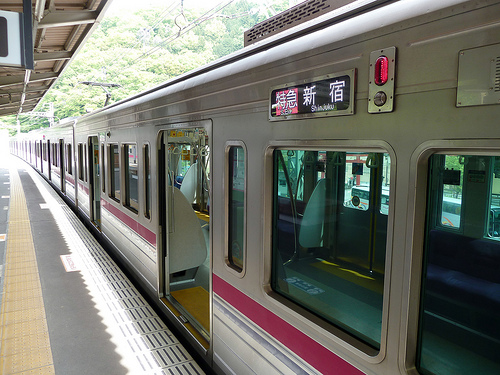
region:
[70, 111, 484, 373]
The train is parked at the station.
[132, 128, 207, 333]
The door is open on the train.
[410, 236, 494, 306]
The seats in the train are blue.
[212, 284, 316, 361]
The train has a red line across the side.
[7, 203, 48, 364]
Part of the sidewalk is yellow.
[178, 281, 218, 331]
The doorway step is yellow.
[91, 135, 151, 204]
The train has windows.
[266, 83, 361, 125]
The sign is in Chinese.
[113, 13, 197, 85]
Wires are above the train.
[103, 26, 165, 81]
The green trees are in the background.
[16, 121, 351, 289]
The train has windows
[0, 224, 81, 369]
The floor is tiled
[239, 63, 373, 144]
The train has characters on it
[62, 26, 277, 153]
The trees are in the back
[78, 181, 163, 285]
The train has a red stripe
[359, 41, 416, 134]
The light is off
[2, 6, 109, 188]
The ceiling covers the floor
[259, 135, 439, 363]
No one is in this window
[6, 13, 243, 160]
Trees are growing in the back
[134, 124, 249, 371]
The door is open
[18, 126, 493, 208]
The train is large.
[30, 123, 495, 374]
Many windows are on the train.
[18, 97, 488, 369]
The train is grey and red.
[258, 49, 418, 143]
The lettering is lit up.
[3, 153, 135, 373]
The station is barren.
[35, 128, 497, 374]
There is no one on the train.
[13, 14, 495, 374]
It is a nice and clear day.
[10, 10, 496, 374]
The train is not moving.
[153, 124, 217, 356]
The door is open.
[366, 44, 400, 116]
The light is red.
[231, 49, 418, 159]
the writing is japanese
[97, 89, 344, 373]
a subway train car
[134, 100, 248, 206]
subway hanger straps in a car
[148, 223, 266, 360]
the train has a yellow step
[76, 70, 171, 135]
power lines for the train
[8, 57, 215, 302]
the train is at a station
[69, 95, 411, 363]
the doors are open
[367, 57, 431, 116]
the light is red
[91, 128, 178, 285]
the train has a red stripe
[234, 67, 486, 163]
the letters are white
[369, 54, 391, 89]
a red light on the train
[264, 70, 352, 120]
writing on the sign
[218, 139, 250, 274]
a window on the train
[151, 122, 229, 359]
the doors of the train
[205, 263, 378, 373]
a red stripe on the train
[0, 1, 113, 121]
a brown roof overhead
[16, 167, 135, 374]
a shadow on the ground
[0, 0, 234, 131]
wires over the train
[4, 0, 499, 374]
a long gray train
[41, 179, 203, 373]
a vent near the train